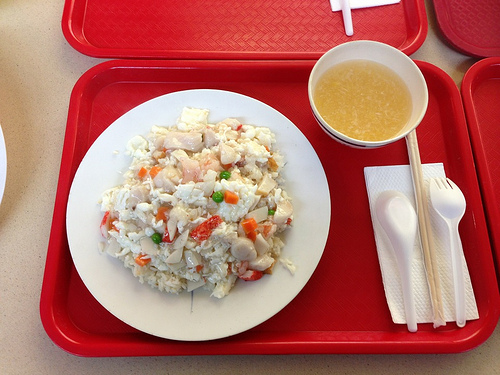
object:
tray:
[38, 59, 500, 358]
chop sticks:
[404, 128, 447, 327]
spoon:
[377, 190, 420, 333]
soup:
[316, 59, 416, 143]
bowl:
[307, 39, 430, 150]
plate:
[64, 88, 333, 343]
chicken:
[174, 152, 201, 185]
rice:
[136, 141, 162, 166]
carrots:
[242, 217, 273, 244]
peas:
[209, 169, 233, 204]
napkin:
[363, 162, 479, 326]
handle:
[401, 255, 421, 334]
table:
[0, 2, 499, 374]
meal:
[97, 105, 297, 300]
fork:
[429, 175, 468, 330]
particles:
[375, 71, 388, 86]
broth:
[328, 72, 361, 120]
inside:
[354, 57, 415, 88]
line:
[310, 111, 366, 150]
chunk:
[221, 144, 235, 165]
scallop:
[231, 238, 257, 262]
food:
[231, 154, 271, 213]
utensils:
[381, 129, 468, 332]